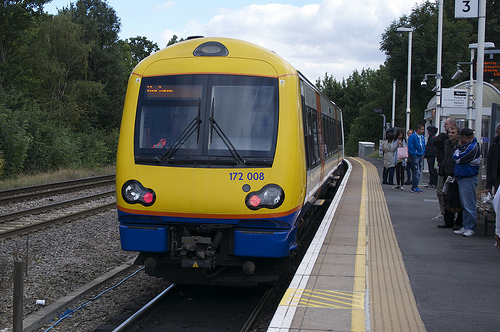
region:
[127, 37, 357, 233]
light rail train on tracks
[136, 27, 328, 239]
yellow and blue train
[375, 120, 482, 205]
many people on a train platform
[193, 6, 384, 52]
fluffy clouds in the sky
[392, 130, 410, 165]
woman holding pink bag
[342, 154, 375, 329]
yellow stripe on a sidewalk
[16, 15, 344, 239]
trees next to a train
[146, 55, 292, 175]
windows on a train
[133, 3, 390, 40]
cloud in the white sky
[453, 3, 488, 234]
man standing by a white pole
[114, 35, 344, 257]
light rail train painted in red, yellow and blue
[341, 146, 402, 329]
light rail station platform painted yellow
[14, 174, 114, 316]
light rail train tracks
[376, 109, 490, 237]
people waiting to board light rail train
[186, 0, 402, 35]
bright blue sky with white clouds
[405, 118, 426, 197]
man in blue jeans and blue jacket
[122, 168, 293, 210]
light rail train headlights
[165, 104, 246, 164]
light rail train windshield wipers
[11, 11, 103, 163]
trees growing alongside of light rail tracks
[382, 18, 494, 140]
pole lights at light rail station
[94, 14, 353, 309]
train on train track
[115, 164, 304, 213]
headlights on front of train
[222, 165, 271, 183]
number on front of train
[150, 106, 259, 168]
windshield wipers on train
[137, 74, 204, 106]
digital window at top of train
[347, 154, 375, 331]
yellow line on train platform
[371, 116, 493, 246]
people standing on train platform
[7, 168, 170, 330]
gravel on ground surrounding train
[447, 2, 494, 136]
number on pole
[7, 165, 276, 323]
three sets of train tracks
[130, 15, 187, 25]
patch of sky with no clouds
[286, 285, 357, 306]
yellow striped block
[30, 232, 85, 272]
bed of rocks for train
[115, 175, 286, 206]
signaling lights for train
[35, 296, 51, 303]
white piece of debris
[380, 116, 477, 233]
people waiting for train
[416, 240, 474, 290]
paved slab of sidewalk for people to stand at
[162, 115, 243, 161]
windshield wipers for clearing windows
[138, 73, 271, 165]
windows for conductor to see from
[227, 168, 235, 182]
black number on train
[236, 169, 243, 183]
black number on train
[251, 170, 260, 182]
black number on train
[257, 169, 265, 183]
black number on train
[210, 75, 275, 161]
tinted window on bus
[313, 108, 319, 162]
tinted window on bus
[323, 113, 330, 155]
tinted window on bus